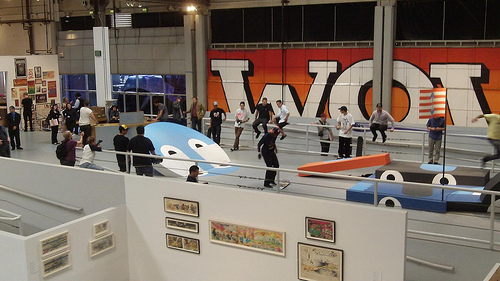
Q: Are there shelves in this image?
A: No, there are no shelves.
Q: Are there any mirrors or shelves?
A: No, there are no shelves or mirrors.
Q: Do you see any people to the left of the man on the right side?
A: Yes, there is a person to the left of the man.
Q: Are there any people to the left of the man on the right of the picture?
A: Yes, there is a person to the left of the man.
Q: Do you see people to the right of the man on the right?
A: No, the person is to the left of the man.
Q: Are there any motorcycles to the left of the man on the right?
A: No, there is a person to the left of the man.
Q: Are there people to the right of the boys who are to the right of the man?
A: Yes, there is a person to the right of the boys.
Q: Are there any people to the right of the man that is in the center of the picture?
A: Yes, there is a person to the right of the man.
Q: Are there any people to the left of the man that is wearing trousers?
A: No, the person is to the right of the man.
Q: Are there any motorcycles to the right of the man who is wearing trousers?
A: No, there is a person to the right of the man.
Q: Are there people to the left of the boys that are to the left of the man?
A: Yes, there is a person to the left of the boys.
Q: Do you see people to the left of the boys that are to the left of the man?
A: Yes, there is a person to the left of the boys.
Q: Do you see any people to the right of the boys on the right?
A: No, the person is to the left of the boys.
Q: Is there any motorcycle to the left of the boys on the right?
A: No, there is a person to the left of the boys.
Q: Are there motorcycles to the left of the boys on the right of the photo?
A: No, there is a person to the left of the boys.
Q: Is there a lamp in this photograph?
A: No, there are no lamps.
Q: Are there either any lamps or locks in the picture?
A: No, there are no lamps or locks.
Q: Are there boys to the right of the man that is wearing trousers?
A: Yes, there are boys to the right of the man.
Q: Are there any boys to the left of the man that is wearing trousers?
A: No, the boys are to the right of the man.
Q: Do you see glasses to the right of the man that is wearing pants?
A: No, there are boys to the right of the man.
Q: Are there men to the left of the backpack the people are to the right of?
A: Yes, there is a man to the left of the backpack.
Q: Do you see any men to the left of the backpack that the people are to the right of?
A: Yes, there is a man to the left of the backpack.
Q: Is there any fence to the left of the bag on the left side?
A: No, there is a man to the left of the backpack.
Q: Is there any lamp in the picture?
A: No, there are no lamps.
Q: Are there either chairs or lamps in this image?
A: No, there are no lamps or chairs.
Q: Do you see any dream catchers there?
A: No, there are no dream catchers.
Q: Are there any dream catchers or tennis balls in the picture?
A: No, there are no dream catchers or tennis balls.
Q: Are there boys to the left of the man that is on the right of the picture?
A: Yes, there are boys to the left of the man.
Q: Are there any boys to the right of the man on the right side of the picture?
A: No, the boys are to the left of the man.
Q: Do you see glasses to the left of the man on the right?
A: No, there are boys to the left of the man.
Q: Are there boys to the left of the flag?
A: Yes, there are boys to the left of the flag.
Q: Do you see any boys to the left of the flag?
A: Yes, there are boys to the left of the flag.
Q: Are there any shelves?
A: No, there are no shelves.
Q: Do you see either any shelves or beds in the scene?
A: No, there are no shelves or beds.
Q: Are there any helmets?
A: No, there are no helmets.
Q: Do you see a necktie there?
A: No, there are no ties.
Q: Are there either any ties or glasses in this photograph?
A: No, there are no ties or glasses.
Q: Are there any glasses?
A: No, there are no glasses.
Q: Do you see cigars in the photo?
A: No, there are no cigars.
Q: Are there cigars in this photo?
A: No, there are no cigars.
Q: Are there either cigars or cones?
A: No, there are no cigars or cones.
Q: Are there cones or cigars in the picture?
A: No, there are no cigars or cones.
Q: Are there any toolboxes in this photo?
A: No, there are no toolboxes.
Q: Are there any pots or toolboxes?
A: No, there are no toolboxes or pots.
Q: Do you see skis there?
A: No, there are no skis.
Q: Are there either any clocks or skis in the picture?
A: No, there are no skis or clocks.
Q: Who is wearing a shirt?
A: The man is wearing a shirt.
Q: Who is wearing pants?
A: The man is wearing pants.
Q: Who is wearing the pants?
A: The man is wearing pants.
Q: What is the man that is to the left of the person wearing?
A: The man is wearing pants.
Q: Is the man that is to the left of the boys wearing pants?
A: Yes, the man is wearing pants.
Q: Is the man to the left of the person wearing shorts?
A: No, the man is wearing pants.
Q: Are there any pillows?
A: No, there are no pillows.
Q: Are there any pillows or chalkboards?
A: No, there are no pillows or chalkboards.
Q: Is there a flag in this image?
A: Yes, there is a flag.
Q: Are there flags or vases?
A: Yes, there is a flag.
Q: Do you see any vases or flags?
A: Yes, there is a flag.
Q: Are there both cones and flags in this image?
A: No, there is a flag but no cones.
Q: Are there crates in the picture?
A: No, there are no crates.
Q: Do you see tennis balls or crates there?
A: No, there are no crates or tennis balls.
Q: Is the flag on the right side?
A: Yes, the flag is on the right of the image.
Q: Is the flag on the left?
A: No, the flag is on the right of the image.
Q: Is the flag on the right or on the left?
A: The flag is on the right of the image.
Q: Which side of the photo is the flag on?
A: The flag is on the right of the image.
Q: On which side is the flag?
A: The flag is on the right of the image.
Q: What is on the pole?
A: The flag is on the pole.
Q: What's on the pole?
A: The flag is on the pole.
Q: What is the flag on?
A: The flag is on the pole.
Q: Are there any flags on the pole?
A: Yes, there is a flag on the pole.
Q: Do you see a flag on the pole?
A: Yes, there is a flag on the pole.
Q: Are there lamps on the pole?
A: No, there is a flag on the pole.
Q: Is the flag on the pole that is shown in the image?
A: Yes, the flag is on the pole.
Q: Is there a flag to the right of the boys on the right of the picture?
A: Yes, there is a flag to the right of the boys.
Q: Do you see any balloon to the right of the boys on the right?
A: No, there is a flag to the right of the boys.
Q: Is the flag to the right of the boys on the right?
A: Yes, the flag is to the right of the boys.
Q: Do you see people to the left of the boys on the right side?
A: Yes, there is a person to the left of the boys.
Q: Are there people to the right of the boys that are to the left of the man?
A: No, the person is to the left of the boys.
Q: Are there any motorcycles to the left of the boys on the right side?
A: No, there is a person to the left of the boys.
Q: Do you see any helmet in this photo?
A: No, there are no helmets.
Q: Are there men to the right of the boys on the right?
A: Yes, there is a man to the right of the boys.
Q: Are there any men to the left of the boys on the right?
A: No, the man is to the right of the boys.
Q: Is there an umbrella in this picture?
A: No, there are no umbrellas.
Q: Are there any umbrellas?
A: No, there are no umbrellas.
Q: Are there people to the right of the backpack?
A: Yes, there are people to the right of the backpack.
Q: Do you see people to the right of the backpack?
A: Yes, there are people to the right of the backpack.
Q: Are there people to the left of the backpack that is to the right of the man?
A: No, the people are to the right of the backpack.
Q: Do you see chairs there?
A: No, there are no chairs.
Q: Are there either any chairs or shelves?
A: No, there are no chairs or shelves.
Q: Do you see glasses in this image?
A: No, there are no glasses.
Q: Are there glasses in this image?
A: No, there are no glasses.